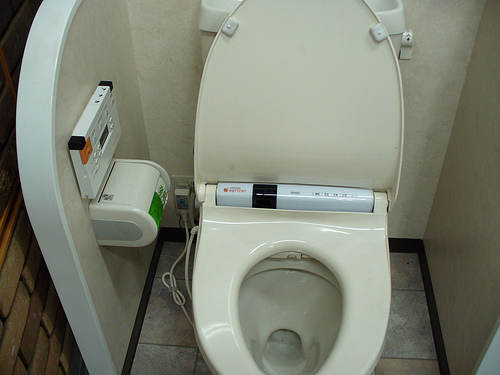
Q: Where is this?
A: A bathroom.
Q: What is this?
A: A toilet.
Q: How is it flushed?
A: It looks like it is automatic.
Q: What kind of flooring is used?
A: Tile.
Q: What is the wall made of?
A: Brick.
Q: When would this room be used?
A: If you need to use the toilet.